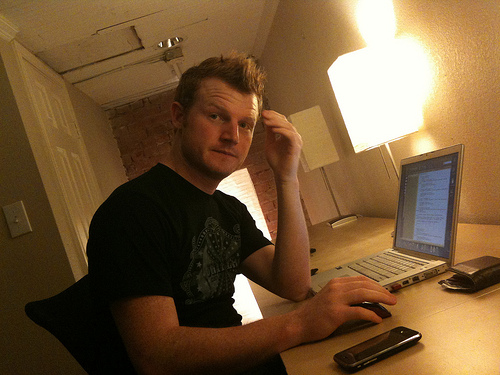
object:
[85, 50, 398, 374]
man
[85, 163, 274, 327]
shirt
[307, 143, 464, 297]
laptop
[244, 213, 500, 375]
desk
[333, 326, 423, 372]
phone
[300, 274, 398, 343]
right hand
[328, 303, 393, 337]
mouse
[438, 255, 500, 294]
wallet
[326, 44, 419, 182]
lamp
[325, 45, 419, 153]
shade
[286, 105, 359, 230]
lamp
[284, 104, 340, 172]
shade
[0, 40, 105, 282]
door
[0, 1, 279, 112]
ceiling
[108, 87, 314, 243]
wall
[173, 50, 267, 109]
hair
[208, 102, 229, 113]
brow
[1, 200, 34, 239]
light switch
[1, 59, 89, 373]
wall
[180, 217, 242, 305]
design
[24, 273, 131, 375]
chair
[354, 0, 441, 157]
reflection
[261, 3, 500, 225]
wall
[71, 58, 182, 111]
attic access